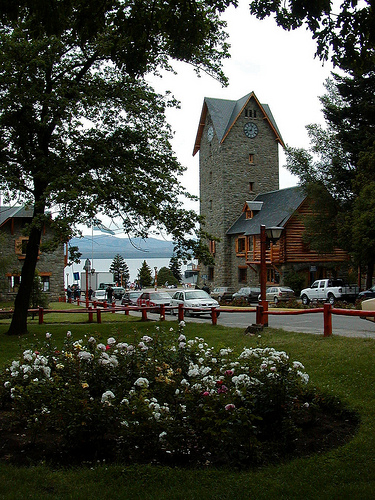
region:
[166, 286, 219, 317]
this is a car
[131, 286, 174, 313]
this is a car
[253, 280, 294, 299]
this is a car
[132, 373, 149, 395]
this is a flower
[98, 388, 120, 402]
this is a flower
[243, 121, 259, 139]
Grey and black more visible clock.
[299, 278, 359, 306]
A large white truck.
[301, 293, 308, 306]
Front driver tire on a white truck.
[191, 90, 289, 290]
A tall brown clock tower with 2 clocks.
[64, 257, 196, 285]
Grey body of water.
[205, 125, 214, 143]
Less visible clock on the side of a tower.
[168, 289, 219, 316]
Most visible white car parked this way.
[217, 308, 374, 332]
A grey road.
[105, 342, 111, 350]
The reddest flower amongst the white ones.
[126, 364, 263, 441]
these are lots of flowers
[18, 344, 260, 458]
the flower are growing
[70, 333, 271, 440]
the flower are mostly white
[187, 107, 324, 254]
the building is tall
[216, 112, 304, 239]
the building is brick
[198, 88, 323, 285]
the building is gray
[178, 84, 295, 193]
this is a clocktower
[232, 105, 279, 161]
the clock is gray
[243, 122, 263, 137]
a round clock on a building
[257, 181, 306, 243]
a black shingled roof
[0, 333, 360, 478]
a round flower bed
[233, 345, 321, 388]
a batch of white flowers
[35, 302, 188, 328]
a short wood fence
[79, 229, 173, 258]
a mountain covered with trees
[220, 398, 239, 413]
a pink flower in a flower bed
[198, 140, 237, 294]
a rock building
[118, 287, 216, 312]
three cars parked on the side of a street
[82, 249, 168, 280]
a large body of water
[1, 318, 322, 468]
area of bushes in grass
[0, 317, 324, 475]
bushes hold a lot of flowers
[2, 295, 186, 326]
fence railing around building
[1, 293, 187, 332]
fence railing is red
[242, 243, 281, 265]
balcony on side of building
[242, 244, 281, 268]
balcony rails are log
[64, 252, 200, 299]
water behind the buildings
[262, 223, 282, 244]
lamp attached to post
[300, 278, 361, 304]
The white pickup truck.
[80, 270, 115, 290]
The white box truck.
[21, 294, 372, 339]
The red wooden post fence.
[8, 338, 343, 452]
The white flowers in the grass area.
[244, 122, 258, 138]
the clock is large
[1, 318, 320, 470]
the flowers are multi colored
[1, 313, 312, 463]
the flowers are white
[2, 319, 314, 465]
the flowers are yellow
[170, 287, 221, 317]
the car is parked